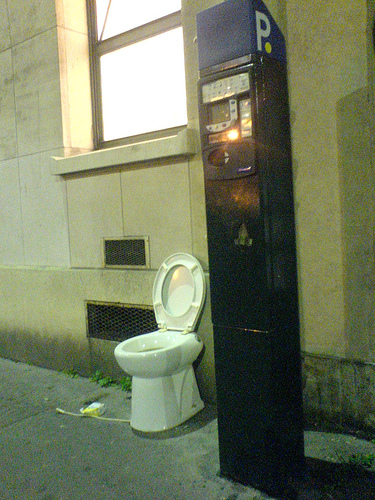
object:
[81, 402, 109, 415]
box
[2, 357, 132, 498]
ground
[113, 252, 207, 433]
toilet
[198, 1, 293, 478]
meter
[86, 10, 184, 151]
window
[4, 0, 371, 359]
building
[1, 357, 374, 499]
sidewalk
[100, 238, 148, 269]
vent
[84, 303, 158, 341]
vent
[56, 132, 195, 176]
window sill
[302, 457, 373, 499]
shadow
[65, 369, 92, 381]
weeds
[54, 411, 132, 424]
hose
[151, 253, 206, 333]
lid